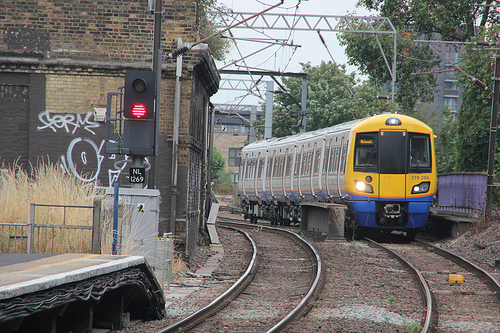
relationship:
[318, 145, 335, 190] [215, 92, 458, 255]
window on train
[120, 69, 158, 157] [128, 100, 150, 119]
signal with light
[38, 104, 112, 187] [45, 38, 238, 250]
graffiti on building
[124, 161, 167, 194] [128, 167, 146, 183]
nl 1269 on nl 1269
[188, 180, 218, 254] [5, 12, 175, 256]
pipes on side of building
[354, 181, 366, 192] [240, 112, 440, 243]
headlight on train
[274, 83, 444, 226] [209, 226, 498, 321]
engine on track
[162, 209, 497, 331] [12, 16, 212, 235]
tracks curving around building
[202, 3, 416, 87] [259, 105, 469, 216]
scaffolding above train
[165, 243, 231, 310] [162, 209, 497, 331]
cement next to tracks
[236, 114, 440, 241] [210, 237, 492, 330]
train next to track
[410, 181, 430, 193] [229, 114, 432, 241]
headlights on train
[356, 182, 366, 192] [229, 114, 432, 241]
headlight on train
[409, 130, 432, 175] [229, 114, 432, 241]
window on train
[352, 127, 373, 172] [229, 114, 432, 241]
window on train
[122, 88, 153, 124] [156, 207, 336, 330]
light near track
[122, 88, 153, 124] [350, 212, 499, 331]
light near track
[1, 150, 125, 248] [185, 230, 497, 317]
plant near track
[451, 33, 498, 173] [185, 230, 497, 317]
plant near track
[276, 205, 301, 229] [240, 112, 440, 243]
wheels on train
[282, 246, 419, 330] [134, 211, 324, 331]
rocks on track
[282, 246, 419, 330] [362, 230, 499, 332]
rocks on track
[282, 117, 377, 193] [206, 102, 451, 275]
windows on train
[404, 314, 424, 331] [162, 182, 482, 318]
grass on track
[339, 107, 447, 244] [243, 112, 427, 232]
front end on a train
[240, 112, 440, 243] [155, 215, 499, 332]
train coming down track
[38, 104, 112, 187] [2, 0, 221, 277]
graffiti on side of a building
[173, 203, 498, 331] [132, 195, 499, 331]
tracks in dirt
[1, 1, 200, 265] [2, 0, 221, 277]
brick wall of a building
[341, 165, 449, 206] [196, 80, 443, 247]
headlights on a train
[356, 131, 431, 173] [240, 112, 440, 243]
front windows on a train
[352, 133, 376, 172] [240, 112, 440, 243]
window on side of a train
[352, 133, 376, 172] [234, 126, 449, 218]
window of a train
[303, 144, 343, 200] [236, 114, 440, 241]
window of a train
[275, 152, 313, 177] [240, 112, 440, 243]
window of a train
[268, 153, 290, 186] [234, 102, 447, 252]
window of a train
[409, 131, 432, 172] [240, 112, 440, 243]
window of a train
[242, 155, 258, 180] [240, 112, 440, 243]
window of a train